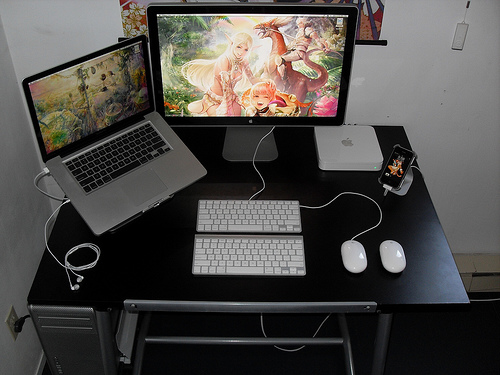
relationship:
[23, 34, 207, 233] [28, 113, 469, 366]
laptop on computer desk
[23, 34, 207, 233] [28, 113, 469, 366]
apple laptop on computer desk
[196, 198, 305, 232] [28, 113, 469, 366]
keyboard on computer desk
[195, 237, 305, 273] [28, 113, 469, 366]
keyboard on computer desk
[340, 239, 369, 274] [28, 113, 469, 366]
computer mice on computer desk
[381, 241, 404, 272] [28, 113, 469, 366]
computer mouse on computer desk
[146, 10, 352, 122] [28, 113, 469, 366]
apple monitor on computer desk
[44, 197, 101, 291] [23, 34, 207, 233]
earbuds sticking out of laptop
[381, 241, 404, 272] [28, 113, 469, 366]
wireless mouse on computer desk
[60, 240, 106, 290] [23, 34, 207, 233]
ear buds for computer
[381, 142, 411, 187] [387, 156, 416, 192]
cell phone on charger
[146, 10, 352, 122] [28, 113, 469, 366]
computer monitor on computer desk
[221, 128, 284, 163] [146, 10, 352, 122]
base of monitor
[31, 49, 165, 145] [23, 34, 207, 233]
moniter of laptop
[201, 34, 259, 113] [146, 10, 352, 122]
girl photo on computer monitor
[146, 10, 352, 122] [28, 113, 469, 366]
desk top computer on computer desk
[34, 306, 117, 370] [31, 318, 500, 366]
computer tower on ground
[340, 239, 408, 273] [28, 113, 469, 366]
computer mice on computer desk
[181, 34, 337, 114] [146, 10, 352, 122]
fantasy scene on desktop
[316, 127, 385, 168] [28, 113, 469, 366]
wireless router on computer desk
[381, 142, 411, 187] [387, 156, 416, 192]
smart phone connected to charger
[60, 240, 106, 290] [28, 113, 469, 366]
ear bud headphones on computer desk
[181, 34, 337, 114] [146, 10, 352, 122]
apple monitor on computer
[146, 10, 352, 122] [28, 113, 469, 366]
mac monitor on computer desk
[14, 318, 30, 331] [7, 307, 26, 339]
plug connected to outlet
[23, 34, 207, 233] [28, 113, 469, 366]
mac laptop on computer desk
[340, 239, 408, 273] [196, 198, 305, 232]
two mouses by keyboard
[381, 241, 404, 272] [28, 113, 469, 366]
cordless mouse on computer desk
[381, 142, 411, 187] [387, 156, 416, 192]
phone on charger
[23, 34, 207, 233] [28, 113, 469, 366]
laptop sitting on computer desk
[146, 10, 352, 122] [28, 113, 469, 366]
monitor sitting on computer desk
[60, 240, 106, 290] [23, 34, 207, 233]
ear buds plugged into computer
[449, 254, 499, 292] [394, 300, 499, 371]
wall heater on floor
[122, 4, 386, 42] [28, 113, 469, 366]
picture on wall behind computer desk